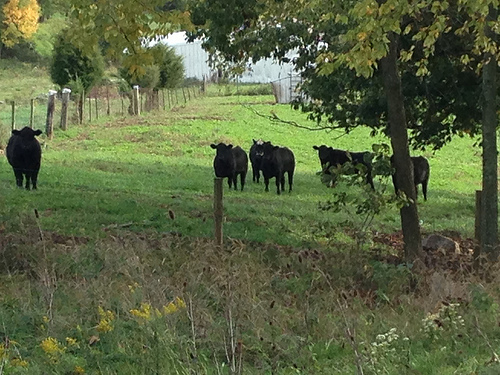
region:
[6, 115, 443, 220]
a bunch of cows standing around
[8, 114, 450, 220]
several black angus cows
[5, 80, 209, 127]
a fence with wooden posts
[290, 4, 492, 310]
a tree in front of cows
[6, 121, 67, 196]
one cow stands alone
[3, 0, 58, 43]
yellow leaves on a tree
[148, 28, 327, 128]
a large white building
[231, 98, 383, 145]
a branch with no leaves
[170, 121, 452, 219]
several cows standing together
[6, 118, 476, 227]
black cows standing in the grass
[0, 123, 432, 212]
cows standing in a field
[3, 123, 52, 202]
one black cow standing alone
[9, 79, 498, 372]
a green grassy field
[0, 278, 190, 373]
cluster of yellow flowers in the grass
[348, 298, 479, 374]
cluster of white flowers in the grass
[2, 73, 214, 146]
wooden fence bounding the field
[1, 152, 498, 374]
shaded area in the field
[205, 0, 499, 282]
two trees shading the cows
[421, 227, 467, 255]
rock on the ground between two trees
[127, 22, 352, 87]
white building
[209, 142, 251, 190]
Black cow four legs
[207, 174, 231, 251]
A wooden fence post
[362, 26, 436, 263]
A tall tree trunk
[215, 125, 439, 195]
A group of cattle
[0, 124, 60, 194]
A cow standing in field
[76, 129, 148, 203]
A green grassy field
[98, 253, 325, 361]
Weeds growing in field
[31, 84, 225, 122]
A fence along the edge of field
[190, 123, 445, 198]
A group of black cows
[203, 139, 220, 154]
The ear of a cow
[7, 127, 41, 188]
A black bovine looking ahead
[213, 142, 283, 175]
Cattle looking up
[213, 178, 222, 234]
A wooden post in the ground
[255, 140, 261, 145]
A white spot on the head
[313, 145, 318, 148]
An ear sticking out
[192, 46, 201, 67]
A whitish surface in the background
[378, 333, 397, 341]
Whitish flowers in the grass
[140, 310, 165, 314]
Yellowish flowers in the grass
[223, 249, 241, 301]
Dried up plants in the grass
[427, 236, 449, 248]
A piece of rock on the ground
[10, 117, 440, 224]
cows in a field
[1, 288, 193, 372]
yellow flowers in the grass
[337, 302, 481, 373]
white flowers in the grass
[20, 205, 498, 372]
this grass is going to seed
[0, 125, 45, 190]
this cow is black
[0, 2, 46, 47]
a yellow tree on the hill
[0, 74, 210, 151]
a fence at the edge of the field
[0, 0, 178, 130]
a hill on the left of the field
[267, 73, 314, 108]
a fence behind the cows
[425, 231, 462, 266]
a rock on the ground